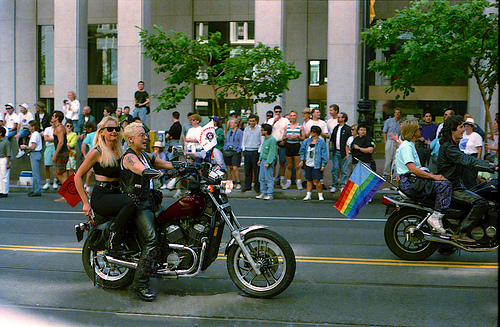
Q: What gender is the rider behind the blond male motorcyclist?
A: Female.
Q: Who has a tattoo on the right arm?
A: Blonde male.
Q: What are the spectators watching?
A: Motorcyclists.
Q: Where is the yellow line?
A: In the middle of the road?.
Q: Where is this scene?
A: A city street.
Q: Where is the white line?
A: On the edge of the road.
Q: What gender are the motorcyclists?
A: Female.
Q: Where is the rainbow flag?
A: On the back of a motorcycle.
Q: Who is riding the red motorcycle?
A: Two women.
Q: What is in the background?
A: A building.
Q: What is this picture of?
A: Bikers.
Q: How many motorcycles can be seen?
A: 2.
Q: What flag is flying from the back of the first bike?
A: Gay Pride.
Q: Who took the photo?
A: An on looker.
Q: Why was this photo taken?
A: To show the bikes.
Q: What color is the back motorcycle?
A: Maroon.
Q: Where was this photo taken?
A: During a parade.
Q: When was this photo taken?
A: During the day.